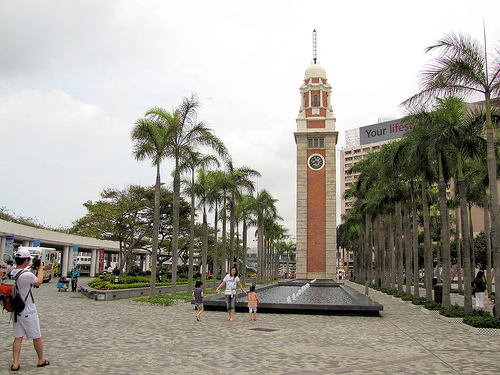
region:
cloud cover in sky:
[2, 3, 494, 253]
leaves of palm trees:
[132, 95, 277, 297]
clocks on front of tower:
[292, 31, 334, 277]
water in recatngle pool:
[202, 274, 379, 312]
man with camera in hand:
[10, 248, 49, 370]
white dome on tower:
[302, 65, 329, 83]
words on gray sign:
[357, 112, 429, 150]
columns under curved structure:
[4, 227, 126, 277]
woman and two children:
[195, 267, 258, 319]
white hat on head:
[13, 248, 35, 265]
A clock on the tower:
[305, 153, 325, 173]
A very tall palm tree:
[131, 105, 166, 298]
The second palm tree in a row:
[167, 110, 187, 301]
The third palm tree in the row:
[183, 145, 204, 290]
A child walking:
[246, 281, 268, 324]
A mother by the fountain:
[220, 262, 247, 322]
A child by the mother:
[188, 275, 222, 324]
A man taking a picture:
[3, 247, 56, 372]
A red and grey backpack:
[0, 274, 35, 321]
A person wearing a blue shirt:
[68, 260, 83, 292]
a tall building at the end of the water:
[223, 13, 418, 374]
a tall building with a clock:
[282, 16, 384, 313]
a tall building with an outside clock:
[265, 20, 415, 310]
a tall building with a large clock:
[280, 7, 390, 252]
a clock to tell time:
[255, 110, 355, 201]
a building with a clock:
[283, 30, 368, 295]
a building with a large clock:
[272, 8, 383, 233]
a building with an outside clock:
[249, 11, 392, 279]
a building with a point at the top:
[264, 5, 379, 287]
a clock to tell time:
[268, 15, 415, 290]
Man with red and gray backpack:
[0, 247, 52, 372]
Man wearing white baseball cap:
[1, 244, 52, 371]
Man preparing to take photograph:
[1, 245, 52, 372]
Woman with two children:
[190, 264, 262, 324]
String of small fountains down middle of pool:
[197, 275, 387, 319]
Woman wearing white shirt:
[213, 265, 247, 322]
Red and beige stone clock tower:
[290, 26, 338, 281]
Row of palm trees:
[343, 68, 488, 325]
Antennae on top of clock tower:
[292, 28, 340, 281]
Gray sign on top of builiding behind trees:
[338, 96, 497, 277]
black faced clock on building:
[306, 153, 326, 172]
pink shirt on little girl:
[247, 298, 256, 303]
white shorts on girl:
[246, 308, 255, 312]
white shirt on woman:
[226, 279, 236, 288]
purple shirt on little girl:
[195, 288, 202, 299]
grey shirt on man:
[22, 275, 31, 288]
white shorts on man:
[31, 314, 38, 338]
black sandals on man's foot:
[38, 355, 55, 372]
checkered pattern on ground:
[130, 316, 178, 343]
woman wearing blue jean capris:
[222, 298, 237, 305]